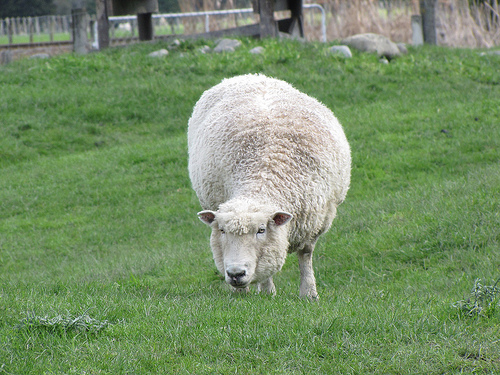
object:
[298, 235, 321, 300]
front legs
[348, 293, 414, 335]
grass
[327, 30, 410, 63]
rocks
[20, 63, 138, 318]
field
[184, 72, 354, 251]
round body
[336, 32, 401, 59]
boulder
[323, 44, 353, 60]
boulder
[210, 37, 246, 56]
boulder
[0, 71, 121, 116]
grass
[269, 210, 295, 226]
ear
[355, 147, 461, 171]
grass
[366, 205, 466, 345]
glass table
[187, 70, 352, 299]
sheep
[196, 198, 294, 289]
head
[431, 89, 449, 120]
ground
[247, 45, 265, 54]
boulder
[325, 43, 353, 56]
boulder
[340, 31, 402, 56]
boulder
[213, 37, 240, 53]
boulder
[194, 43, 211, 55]
boulder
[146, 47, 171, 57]
boulder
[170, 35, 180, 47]
boulder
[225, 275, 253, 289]
sheep mouth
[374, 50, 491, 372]
grass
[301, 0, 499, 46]
hay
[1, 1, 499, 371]
pasture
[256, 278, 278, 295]
leg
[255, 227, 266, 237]
eye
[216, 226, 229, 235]
eye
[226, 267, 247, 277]
nose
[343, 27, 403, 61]
rock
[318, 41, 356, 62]
rock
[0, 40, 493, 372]
field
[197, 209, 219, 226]
ear